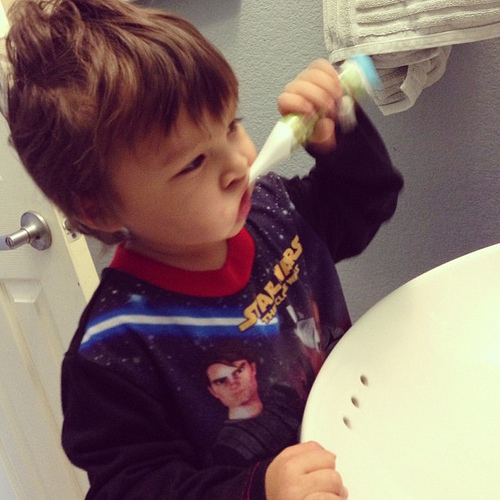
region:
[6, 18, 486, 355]
little boy brushing teeth by white sink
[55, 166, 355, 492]
boy wearing shirt about future fighters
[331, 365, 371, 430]
three dark oval holes on sink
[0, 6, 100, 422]
silver knob on white door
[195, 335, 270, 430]
serious expression under slanted eyebrows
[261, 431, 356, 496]
hand curled around edge of sink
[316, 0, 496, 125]
edges of gray towel hanging on wall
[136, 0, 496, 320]
textured grey bathroom wall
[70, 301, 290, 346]
blue and white stripe across shirt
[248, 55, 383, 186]
hand curled around toothbrush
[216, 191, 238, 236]
The brush in the boys cheek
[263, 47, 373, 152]
The boy holds onto the brush handle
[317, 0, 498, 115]
The white towel hanging on the wall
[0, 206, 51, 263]
The handle of the bathroom door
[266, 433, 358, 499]
The hand on the sink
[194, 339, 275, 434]
A face on the young buys shirt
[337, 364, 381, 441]
The line of the holes in the sink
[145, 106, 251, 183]
The eyes of the boy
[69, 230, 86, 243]
The screw in the doors bracket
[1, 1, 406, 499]
The boy brushing his teeth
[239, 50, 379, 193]
Blue, green and white electric toothbrush.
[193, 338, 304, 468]
A man on the boy's pajamas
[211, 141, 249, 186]
Nose on a kid's face.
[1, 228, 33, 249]
Silver lever door handle.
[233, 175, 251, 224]
Red lips of a boy brushing his teeth.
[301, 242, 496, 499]
White sink a boy is holding onto.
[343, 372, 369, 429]
Three small drain holes in a white sink.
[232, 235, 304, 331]
Star Wars logo on a boy's shirt.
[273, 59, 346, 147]
A boy's left hand.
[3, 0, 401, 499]
A boy with brown hair brushing his teeth.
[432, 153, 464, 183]
Small part of the blue wall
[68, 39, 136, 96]
Brown hair of the little boy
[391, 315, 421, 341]
Small part of the white sink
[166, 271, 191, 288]
Small red part of boy's shirt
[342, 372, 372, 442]
Three holes in the white sink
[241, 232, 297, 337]
Star wars name on boy's shirt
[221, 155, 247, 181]
Nose of the little boy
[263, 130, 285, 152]
White part of the toothbrush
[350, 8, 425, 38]
Gray towel hung up on rack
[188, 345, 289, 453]
Lex luther body on little boy's shirt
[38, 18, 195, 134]
the hair is brown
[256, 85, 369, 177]
the tooth brush is electric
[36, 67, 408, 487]
the boy is brushing teeth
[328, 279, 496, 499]
the sink is white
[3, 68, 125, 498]
the door is open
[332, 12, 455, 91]
the towel is white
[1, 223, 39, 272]
the handle is silver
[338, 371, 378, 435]
holes are on the sink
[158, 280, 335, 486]
starwars cartoon is on the tshirt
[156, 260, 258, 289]
the neck colar is red